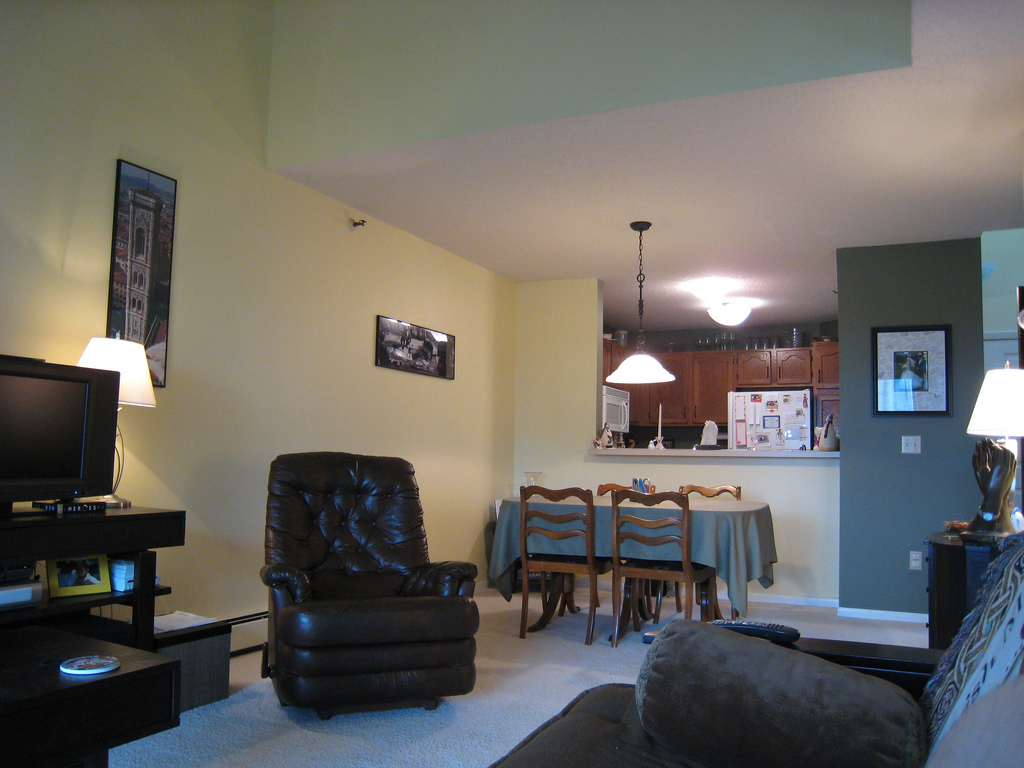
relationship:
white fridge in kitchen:
[728, 387, 812, 451] [585, 314, 842, 461]